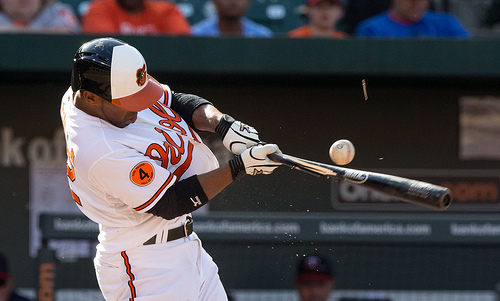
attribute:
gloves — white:
[226, 112, 283, 184]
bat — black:
[267, 143, 461, 213]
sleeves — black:
[158, 84, 219, 245]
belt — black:
[140, 218, 211, 252]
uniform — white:
[40, 89, 234, 286]